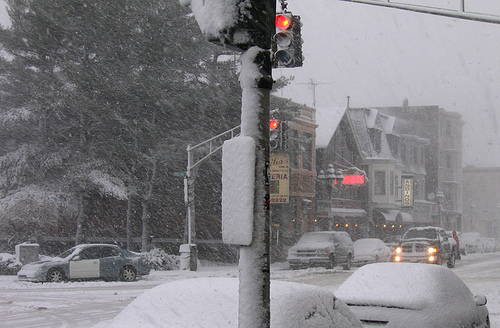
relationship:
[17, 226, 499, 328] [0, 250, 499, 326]
car driving on road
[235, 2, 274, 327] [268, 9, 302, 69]
pole holding traffic light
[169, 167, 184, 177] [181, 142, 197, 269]
sign on pole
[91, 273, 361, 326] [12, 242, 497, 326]
car on road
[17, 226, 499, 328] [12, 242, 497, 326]
car on road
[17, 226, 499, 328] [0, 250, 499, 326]
car on road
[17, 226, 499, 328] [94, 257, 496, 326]
car covered in snow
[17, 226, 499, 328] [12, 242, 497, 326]
car driving on road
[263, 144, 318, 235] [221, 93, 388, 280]
sign on building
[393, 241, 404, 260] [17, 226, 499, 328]
headlight shining from car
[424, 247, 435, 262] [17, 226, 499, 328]
headlight shining from car